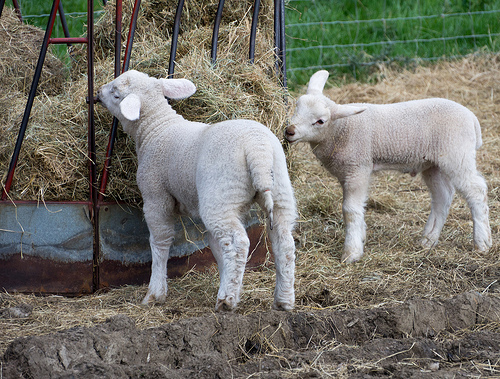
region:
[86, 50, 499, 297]
two baby lambs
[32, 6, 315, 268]
metal feeder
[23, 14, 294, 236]
feeder has hay in it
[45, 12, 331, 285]
metal feeder is red and blue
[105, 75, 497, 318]
lambs are wooly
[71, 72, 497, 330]
baby lambs are eating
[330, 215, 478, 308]
hay is on the ground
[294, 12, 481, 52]
grass is above the lambs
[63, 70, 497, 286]
lambs are a white wooly baby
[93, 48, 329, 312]
baby lamb has his back to us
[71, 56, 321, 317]
the sheep is eating the hay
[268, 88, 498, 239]
the sheep is eating the hay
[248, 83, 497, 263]
the sheep is eating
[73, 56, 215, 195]
the sheep is eating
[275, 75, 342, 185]
the sheep is eating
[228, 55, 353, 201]
the sheep is eating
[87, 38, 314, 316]
the sheep is white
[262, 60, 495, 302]
the sheep is white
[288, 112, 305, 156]
sheep's nose is brown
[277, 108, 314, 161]
sheep's nose is brown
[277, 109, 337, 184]
sheep's nose is brown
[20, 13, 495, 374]
baby lambs eating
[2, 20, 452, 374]
hay is in the food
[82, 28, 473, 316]
the lambs are white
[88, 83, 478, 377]
picture taken outdoors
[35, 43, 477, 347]
picture taken outside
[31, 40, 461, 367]
picture taken during the day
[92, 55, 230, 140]
the lamb's ears are white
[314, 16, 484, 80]
a fence behind the lambs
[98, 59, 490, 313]
two lambs eating food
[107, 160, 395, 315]
the lambs have white legs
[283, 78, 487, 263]
lamb eating the hay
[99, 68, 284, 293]
lamb eating the hay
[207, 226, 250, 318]
leg of the lamb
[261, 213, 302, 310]
leg of the lamb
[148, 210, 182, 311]
leg of the lamb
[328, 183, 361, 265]
leg of the lamb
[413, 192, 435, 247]
leg of the lamb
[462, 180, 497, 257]
leg of the lamb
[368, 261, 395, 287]
patch of brown hay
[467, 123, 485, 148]
tail of the lamb